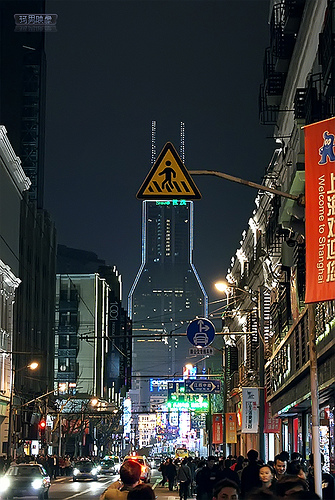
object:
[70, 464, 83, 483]
headlight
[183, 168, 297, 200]
pole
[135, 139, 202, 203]
sign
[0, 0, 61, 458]
building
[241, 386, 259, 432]
banner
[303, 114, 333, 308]
banner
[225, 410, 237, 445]
banner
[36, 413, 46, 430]
traffic light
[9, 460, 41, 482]
windshield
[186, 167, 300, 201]
metal pole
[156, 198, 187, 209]
lights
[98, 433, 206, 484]
car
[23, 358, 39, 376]
light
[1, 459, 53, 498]
car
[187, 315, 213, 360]
sign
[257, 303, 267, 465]
pole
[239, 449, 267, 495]
person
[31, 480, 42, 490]
headlight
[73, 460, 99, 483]
car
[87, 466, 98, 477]
headlight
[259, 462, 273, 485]
head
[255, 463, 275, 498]
person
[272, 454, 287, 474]
head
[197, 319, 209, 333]
arrows